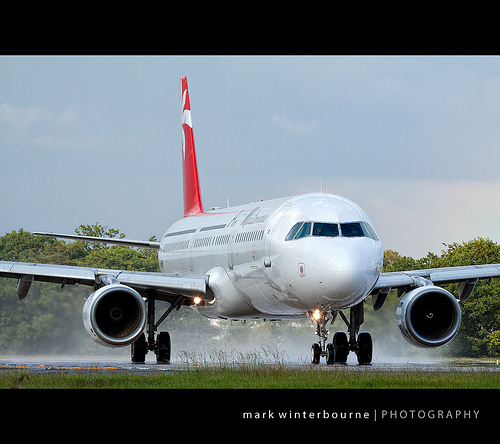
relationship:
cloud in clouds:
[8, 91, 123, 160] [0, 55, 498, 222]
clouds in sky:
[381, 178, 493, 237] [201, 89, 277, 147]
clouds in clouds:
[381, 178, 493, 237] [0, 55, 498, 222]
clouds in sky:
[224, 114, 309, 154] [222, 82, 279, 143]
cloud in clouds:
[0, 100, 118, 158] [0, 55, 498, 222]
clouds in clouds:
[259, 111, 499, 256] [0, 55, 498, 222]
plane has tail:
[4, 199, 498, 378] [172, 71, 207, 212]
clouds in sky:
[233, 84, 399, 176] [5, 53, 435, 164]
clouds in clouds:
[6, 61, 494, 258] [0, 55, 498, 222]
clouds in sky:
[381, 178, 493, 237] [4, 59, 497, 236]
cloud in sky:
[0, 100, 118, 158] [4, 59, 497, 236]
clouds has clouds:
[0, 55, 498, 222] [381, 178, 493, 237]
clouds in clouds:
[262, 103, 330, 150] [0, 55, 498, 222]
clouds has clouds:
[0, 55, 498, 222] [262, 103, 330, 150]